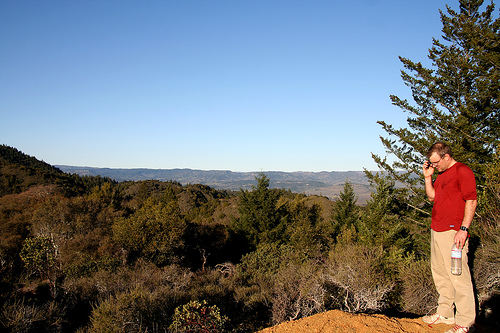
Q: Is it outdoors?
A: Yes, it is outdoors.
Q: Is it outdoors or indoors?
A: It is outdoors.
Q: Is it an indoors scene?
A: No, it is outdoors.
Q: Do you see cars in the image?
A: No, there are no cars.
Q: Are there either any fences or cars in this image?
A: No, there are no cars or fences.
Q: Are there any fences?
A: No, there are no fences.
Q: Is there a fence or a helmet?
A: No, there are no fences or helmets.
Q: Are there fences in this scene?
A: No, there are no fences.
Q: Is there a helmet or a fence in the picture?
A: No, there are no fences or helmets.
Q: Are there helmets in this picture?
A: No, there are no helmets.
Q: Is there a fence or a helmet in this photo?
A: No, there are no helmets or fences.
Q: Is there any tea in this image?
A: No, there is no tea.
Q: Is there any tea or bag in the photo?
A: No, there are no tea or bags.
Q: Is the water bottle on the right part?
A: Yes, the water bottle is on the right of the image.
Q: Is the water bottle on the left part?
A: No, the water bottle is on the right of the image.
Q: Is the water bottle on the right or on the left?
A: The water bottle is on the right of the image.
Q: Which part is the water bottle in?
A: The water bottle is on the right of the image.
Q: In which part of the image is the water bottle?
A: The water bottle is on the right of the image.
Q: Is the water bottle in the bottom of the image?
A: Yes, the water bottle is in the bottom of the image.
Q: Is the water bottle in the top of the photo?
A: No, the water bottle is in the bottom of the image.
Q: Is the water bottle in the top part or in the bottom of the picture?
A: The water bottle is in the bottom of the image.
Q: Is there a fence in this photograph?
A: No, there are no fences.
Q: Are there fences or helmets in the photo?
A: No, there are no fences or helmets.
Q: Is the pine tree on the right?
A: Yes, the pine tree is on the right of the image.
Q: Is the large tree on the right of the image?
A: Yes, the pine tree is on the right of the image.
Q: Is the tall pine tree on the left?
A: No, the pine is on the right of the image.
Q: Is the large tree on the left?
A: No, the pine is on the right of the image.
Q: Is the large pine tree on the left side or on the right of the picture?
A: The pine is on the right of the image.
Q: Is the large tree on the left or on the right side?
A: The pine is on the right of the image.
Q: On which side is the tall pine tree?
A: The pine tree is on the right of the image.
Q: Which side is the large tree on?
A: The pine tree is on the right of the image.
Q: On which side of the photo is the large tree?
A: The pine tree is on the right of the image.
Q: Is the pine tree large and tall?
A: Yes, the pine tree is large and tall.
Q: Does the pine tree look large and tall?
A: Yes, the pine tree is large and tall.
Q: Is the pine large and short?
A: No, the pine is large but tall.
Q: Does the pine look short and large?
A: No, the pine is large but tall.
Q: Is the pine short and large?
A: No, the pine is large but tall.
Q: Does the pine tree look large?
A: Yes, the pine tree is large.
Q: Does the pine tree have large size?
A: Yes, the pine tree is large.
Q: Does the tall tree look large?
A: Yes, the pine tree is large.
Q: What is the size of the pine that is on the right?
A: The pine is large.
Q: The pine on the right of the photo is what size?
A: The pine is large.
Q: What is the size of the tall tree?
A: The pine is large.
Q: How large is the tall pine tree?
A: The pine is large.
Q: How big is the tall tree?
A: The pine is large.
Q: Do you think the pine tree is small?
A: No, the pine tree is large.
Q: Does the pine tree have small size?
A: No, the pine tree is large.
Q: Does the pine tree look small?
A: No, the pine tree is large.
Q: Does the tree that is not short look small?
A: No, the pine tree is large.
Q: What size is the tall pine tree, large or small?
A: The pine is large.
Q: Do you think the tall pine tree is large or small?
A: The pine is large.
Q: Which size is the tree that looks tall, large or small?
A: The pine is large.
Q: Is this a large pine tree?
A: Yes, this is a large pine tree.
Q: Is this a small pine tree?
A: No, this is a large pine tree.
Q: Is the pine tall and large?
A: Yes, the pine is tall and large.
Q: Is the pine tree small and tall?
A: No, the pine tree is tall but large.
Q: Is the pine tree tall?
A: Yes, the pine tree is tall.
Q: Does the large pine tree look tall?
A: Yes, the pine tree is tall.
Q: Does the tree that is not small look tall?
A: Yes, the pine tree is tall.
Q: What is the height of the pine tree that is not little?
A: The pine tree is tall.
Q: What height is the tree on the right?
A: The pine tree is tall.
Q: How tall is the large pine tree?
A: The pine is tall.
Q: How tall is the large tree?
A: The pine is tall.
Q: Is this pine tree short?
A: No, the pine tree is tall.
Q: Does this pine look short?
A: No, the pine is tall.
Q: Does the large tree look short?
A: No, the pine is tall.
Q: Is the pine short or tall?
A: The pine is tall.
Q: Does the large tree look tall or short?
A: The pine is tall.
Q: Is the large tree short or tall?
A: The pine is tall.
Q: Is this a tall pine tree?
A: Yes, this is a tall pine tree.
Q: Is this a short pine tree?
A: No, this is a tall pine tree.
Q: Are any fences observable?
A: No, there are no fences.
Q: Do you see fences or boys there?
A: No, there are no fences or boys.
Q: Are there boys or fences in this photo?
A: No, there are no fences or boys.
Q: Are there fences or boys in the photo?
A: No, there are no fences or boys.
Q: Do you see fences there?
A: No, there are no fences.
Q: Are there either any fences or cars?
A: No, there are no fences or cars.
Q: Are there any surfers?
A: No, there are no surfers.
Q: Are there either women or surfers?
A: No, there are no surfers or women.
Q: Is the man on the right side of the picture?
A: Yes, the man is on the right of the image.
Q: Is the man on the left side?
A: No, the man is on the right of the image.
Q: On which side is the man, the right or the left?
A: The man is on the right of the image.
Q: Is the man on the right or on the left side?
A: The man is on the right of the image.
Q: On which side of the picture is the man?
A: The man is on the right of the image.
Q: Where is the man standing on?
A: The man is standing on the hill.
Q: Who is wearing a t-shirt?
A: The man is wearing a t-shirt.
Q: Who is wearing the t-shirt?
A: The man is wearing a t-shirt.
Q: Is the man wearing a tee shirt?
A: Yes, the man is wearing a tee shirt.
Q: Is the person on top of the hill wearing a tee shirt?
A: Yes, the man is wearing a tee shirt.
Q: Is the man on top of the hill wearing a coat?
A: No, the man is wearing a tee shirt.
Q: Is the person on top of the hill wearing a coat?
A: No, the man is wearing a tee shirt.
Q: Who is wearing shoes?
A: The man is wearing shoes.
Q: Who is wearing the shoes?
A: The man is wearing shoes.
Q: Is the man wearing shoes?
A: Yes, the man is wearing shoes.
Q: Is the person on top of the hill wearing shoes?
A: Yes, the man is wearing shoes.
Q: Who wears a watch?
A: The man wears a watch.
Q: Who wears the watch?
A: The man wears a watch.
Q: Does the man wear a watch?
A: Yes, the man wears a watch.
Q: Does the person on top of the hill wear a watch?
A: Yes, the man wears a watch.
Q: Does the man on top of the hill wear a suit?
A: No, the man wears a watch.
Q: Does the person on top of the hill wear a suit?
A: No, the man wears a watch.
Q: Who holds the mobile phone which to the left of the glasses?
A: The man holds the mobile phone.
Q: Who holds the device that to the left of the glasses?
A: The man holds the mobile phone.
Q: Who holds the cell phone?
A: The man holds the mobile phone.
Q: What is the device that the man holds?
A: The device is a cell phone.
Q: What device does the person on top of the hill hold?
A: The man holds the mobile phone.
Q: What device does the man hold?
A: The man holds the mobile phone.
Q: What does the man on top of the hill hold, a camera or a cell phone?
A: The man holds a cell phone.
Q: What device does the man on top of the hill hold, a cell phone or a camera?
A: The man holds a cell phone.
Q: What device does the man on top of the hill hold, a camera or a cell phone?
A: The man holds a cell phone.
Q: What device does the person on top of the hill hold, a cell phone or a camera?
A: The man holds a cell phone.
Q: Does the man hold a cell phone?
A: Yes, the man holds a cell phone.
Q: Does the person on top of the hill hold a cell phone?
A: Yes, the man holds a cell phone.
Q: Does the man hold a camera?
A: No, the man holds a cell phone.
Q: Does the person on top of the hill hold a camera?
A: No, the man holds a cell phone.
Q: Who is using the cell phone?
A: The man is using the cell phone.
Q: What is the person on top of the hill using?
A: The man is using a cellphone.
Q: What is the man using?
A: The man is using a cellphone.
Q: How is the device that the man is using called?
A: The device is a cell phone.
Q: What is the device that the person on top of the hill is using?
A: The device is a cell phone.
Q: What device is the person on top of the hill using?
A: The man is using a cell phone.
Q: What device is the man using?
A: The man is using a cell phone.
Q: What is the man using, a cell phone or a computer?
A: The man is using a cell phone.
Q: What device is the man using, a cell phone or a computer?
A: The man is using a cell phone.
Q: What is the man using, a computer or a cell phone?
A: The man is using a cell phone.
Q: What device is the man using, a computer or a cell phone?
A: The man is using a cell phone.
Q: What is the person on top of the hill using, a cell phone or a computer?
A: The man is using a cell phone.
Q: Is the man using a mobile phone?
A: Yes, the man is using a mobile phone.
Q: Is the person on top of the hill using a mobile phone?
A: Yes, the man is using a mobile phone.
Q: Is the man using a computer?
A: No, the man is using a mobile phone.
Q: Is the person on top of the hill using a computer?
A: No, the man is using a mobile phone.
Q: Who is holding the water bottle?
A: The man is holding the water bottle.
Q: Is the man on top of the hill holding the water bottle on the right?
A: Yes, the man is holding the water bottle.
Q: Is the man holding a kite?
A: No, the man is holding the water bottle.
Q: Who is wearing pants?
A: The man is wearing pants.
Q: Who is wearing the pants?
A: The man is wearing pants.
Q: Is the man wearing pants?
A: Yes, the man is wearing pants.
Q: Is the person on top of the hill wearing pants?
A: Yes, the man is wearing pants.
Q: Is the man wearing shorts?
A: No, the man is wearing pants.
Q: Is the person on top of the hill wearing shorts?
A: No, the man is wearing pants.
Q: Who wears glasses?
A: The man wears glasses.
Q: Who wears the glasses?
A: The man wears glasses.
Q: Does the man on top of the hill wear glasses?
A: Yes, the man wears glasses.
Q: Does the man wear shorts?
A: No, the man wears glasses.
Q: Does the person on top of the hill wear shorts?
A: No, the man wears glasses.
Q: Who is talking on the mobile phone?
A: The man is talking on the mobile phone.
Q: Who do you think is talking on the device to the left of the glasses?
A: The man is talking on the mobile phone.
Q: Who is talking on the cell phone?
A: The man is talking on the mobile phone.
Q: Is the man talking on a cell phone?
A: Yes, the man is talking on a cell phone.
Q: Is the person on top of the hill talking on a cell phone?
A: Yes, the man is talking on a cell phone.